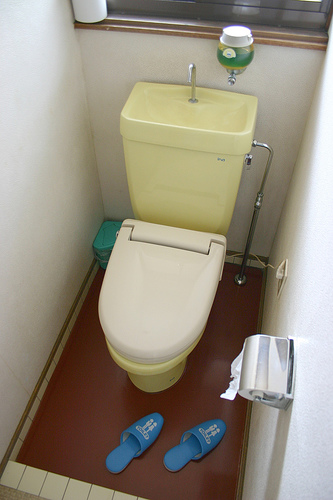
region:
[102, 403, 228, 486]
Blue and white slippers in front of toilet.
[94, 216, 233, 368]
White toilet seat on yellow basin of toilet.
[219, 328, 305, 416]
Toilet roll holder mounted to wall.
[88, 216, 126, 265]
Turquoise trash can on side of toilet.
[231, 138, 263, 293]
Metal piping on the side of the toilet.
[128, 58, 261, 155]
Sink area on top of toilet.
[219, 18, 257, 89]
Soap dispenser above the toilet and sink.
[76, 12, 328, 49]
Wooden windowsill above the sink and soap dispenser.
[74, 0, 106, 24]
Toilet paper roll on wooden windowsill.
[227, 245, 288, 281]
Beige wire plugged into outlet on the wall.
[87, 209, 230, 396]
A toilet inside bathroom.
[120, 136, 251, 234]
Water tank above toilet bowl.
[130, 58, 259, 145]
Sink above water tank.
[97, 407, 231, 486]
Two blue bedroom slippers.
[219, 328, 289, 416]
Toilet paper hanging on wall next to toilet.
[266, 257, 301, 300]
Electrical outlet on wall.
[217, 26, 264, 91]
Soap dispenser on wall behind toilet.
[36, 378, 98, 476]
Brown floor of bathroom.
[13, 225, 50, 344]
White wall of bathroom.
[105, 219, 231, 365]
Closed lid of toilet.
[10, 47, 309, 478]
this is a bathroom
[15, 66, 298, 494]
it is an indoor scene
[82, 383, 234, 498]
slippers are blue in color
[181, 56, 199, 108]
the tap is silver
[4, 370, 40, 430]
the wall is made of tiles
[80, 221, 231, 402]
the toilet is white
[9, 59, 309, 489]
the room is clean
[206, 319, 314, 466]
tissue has been used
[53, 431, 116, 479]
floor is brown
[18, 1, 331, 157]
it is a daytime scene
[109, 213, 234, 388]
The top of the toilet seat is white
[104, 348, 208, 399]
The bottom of the toilet seat is yellow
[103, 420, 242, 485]
The slippers are blue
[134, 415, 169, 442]
The slipper has white pictures and writing on it.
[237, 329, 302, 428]
Toilet paper on the holder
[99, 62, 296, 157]
The sink is above the toilet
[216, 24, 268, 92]
The soap dispenser is green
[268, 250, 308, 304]
A cord plugged into the socket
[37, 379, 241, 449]
The floor is brown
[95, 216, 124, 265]
A blue box next to the toilet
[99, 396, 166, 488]
This is a blue shoe.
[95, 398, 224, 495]
These are blue shoes.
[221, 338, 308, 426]
This is a toilet paper holder.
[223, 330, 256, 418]
This is toilet paper.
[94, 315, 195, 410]
This is a toilet.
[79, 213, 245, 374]
This is a toilet lid.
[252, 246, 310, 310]
This is an outlet.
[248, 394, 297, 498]
This is a shadow.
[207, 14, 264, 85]
This is a soap holder.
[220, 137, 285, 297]
This is a pipe.